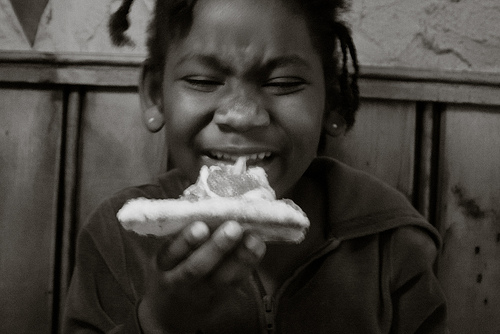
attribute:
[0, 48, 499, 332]
wall — Wooden, paneled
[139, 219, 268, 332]
hand — black, small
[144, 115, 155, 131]
earring — small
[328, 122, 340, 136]
earring — small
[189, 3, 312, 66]
forehead — puffy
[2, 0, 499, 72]
wall — stucco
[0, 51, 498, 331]
paneling — wood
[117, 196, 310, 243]
crust — charred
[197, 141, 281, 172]
mouth — open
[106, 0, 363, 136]
hair — braided